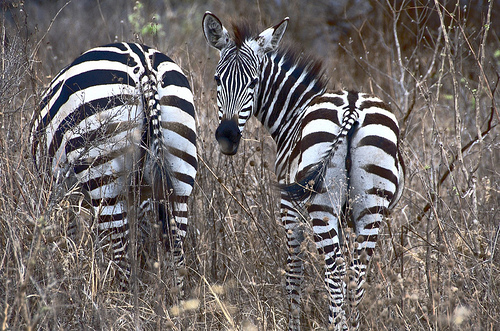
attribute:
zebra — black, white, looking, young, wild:
[200, 9, 408, 331]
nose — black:
[215, 118, 243, 155]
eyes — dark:
[213, 75, 260, 90]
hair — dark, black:
[275, 160, 326, 211]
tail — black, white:
[277, 109, 359, 206]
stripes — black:
[216, 42, 405, 329]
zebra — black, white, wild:
[27, 40, 201, 304]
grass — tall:
[0, 76, 499, 330]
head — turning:
[201, 9, 290, 155]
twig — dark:
[401, 77, 499, 242]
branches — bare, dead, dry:
[385, 1, 499, 246]